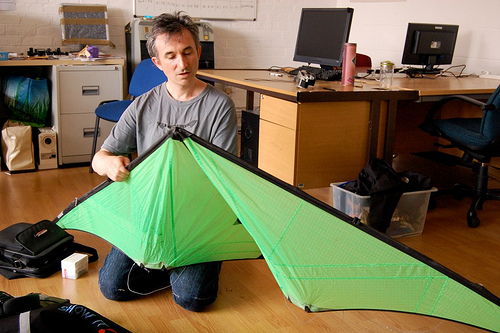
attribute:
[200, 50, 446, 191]
desk — brown , wooden 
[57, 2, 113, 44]
computer screen — covered 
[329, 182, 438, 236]
plastic tote — plastic 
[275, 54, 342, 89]
keyboard — black , computer 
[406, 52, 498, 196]
chair — blue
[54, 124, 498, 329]
kite — green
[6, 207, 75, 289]
briefcase bag — small , black 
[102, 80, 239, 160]
shirt — gray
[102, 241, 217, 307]
jeans — blue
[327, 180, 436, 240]
bin — clear 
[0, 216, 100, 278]
bag — black 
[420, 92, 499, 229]
chair — blue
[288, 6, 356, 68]
monitor — flat screen, black , computer 